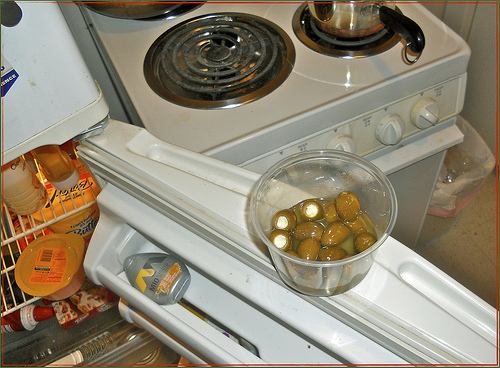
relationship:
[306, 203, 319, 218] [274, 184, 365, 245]
cheese stuffed olive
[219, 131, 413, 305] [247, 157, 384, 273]
round plastic container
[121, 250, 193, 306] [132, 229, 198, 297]
drink energy drink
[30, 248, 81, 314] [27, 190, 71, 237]
ham on shelf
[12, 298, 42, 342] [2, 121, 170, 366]
whip cream bottle in fridge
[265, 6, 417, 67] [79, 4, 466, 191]
pot on white stove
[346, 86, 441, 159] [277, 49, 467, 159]
white button on white stove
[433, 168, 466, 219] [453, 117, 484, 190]
plastic trash bag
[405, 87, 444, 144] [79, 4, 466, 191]
knob on white stove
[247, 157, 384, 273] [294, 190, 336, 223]
container filled stuffed olives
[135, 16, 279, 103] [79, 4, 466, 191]
burner on white stove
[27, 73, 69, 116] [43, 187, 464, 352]
white refrigerator door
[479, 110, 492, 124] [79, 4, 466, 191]
trash can next white stove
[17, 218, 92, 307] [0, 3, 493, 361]
lunch meat in fridge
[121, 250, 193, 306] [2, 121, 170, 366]
drink container in refrigerator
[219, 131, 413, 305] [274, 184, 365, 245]
clear plastic container of food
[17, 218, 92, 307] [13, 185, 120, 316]
yellow plastic top package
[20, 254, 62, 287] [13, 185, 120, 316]
orange ingredient label on package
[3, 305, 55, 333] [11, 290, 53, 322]
can of whipped cream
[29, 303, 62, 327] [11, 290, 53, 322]
long red lid of whipped cream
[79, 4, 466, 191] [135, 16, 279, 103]
white stove metal coils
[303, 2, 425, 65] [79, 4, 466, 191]
pot on white stove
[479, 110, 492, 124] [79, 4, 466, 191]
trash can beside white stove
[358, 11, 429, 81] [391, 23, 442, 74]
pan handle with silver ring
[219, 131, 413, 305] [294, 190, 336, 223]
plastic container with stuffed olives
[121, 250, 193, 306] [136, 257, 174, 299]
drink of mio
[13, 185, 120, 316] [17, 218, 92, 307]
package of bologna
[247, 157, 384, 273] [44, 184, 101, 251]
container of i can't believe it's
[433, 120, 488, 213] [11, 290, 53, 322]
can of whipped cream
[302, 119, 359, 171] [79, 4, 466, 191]
white handle to control white stove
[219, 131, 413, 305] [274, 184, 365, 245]
cup of olives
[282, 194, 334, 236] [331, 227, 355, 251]
olives in liquid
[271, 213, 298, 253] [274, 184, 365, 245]
white cheese inside olive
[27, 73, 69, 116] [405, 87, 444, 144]
white stove knob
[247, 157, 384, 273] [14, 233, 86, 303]
container of ham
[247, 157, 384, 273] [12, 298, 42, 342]
container of whip cream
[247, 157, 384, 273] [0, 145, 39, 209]
container of sweetner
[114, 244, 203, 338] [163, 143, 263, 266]
silver bottle on fridge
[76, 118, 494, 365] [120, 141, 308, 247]
door on unit